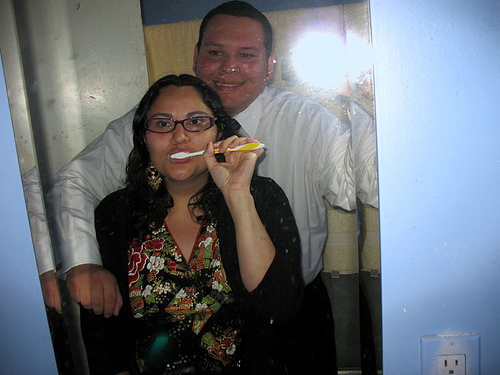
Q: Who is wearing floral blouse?
A: The lady.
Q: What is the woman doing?
A: Brushing teeth.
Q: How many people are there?
A: 2.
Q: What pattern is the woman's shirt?
A: Flowered.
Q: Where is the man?
A: Behind the woman.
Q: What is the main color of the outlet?
A: White.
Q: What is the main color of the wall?
A: Blue.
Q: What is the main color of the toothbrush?
A: White.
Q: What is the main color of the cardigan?
A: Black.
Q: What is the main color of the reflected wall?
A: White.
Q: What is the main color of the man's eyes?
A: Brown.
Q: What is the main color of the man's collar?
A: White.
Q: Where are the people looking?
A: In a mirror.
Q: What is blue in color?
A: The wall.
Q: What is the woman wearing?
A: Black jacket.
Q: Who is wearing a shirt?
A: The man.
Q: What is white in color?
A: The shirt.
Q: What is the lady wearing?
A: Glasses.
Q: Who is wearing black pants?
A: The man.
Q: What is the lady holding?
A: A toothbrush.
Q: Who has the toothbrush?
A: The woman.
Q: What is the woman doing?
A: Brushing her teeth.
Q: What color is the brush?
A: Yellow and white.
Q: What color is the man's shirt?
A: White.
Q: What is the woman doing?
A: Brushing her teeth.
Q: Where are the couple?
A: In the bathroom.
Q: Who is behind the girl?
A: The man.